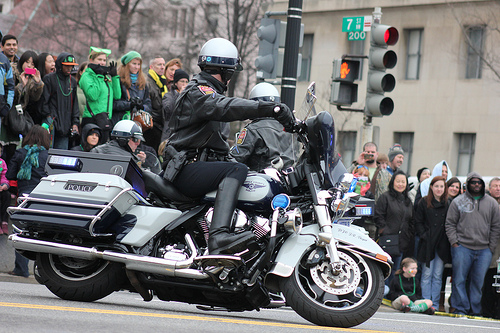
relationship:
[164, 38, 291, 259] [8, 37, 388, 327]
police sitting on motorcycle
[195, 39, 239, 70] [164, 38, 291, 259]
helmet on police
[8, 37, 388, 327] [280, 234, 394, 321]
motorcycle has wheel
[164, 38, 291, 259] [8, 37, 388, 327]
police in picture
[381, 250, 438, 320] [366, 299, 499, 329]
boy sitting on ground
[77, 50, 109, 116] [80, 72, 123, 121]
girl wearing jacket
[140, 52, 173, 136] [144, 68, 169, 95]
man wearing scarf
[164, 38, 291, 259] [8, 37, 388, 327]
police riding motorcycle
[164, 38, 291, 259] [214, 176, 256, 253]
police wearing boots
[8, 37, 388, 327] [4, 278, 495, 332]
motorcycle on road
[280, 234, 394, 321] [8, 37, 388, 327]
wheel on motorcycle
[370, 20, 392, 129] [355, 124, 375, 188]
traffic light on pole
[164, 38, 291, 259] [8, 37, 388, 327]
police on motorcycle